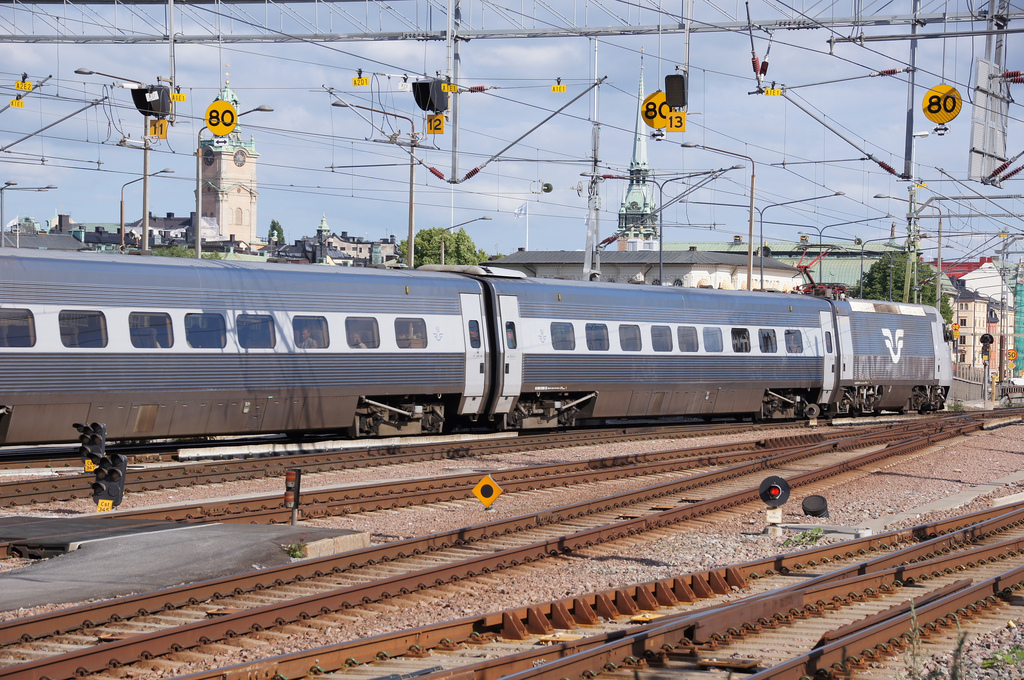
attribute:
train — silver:
[2, 240, 964, 441]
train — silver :
[8, 246, 955, 461]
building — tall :
[192, 86, 257, 246]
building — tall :
[604, 49, 654, 268]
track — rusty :
[8, 403, 998, 522]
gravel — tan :
[21, 451, 747, 518]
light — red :
[760, 472, 791, 511]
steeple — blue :
[620, 60, 666, 257]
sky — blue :
[4, 3, 1016, 306]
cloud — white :
[341, 30, 558, 93]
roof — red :
[944, 258, 986, 272]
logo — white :
[883, 327, 909, 371]